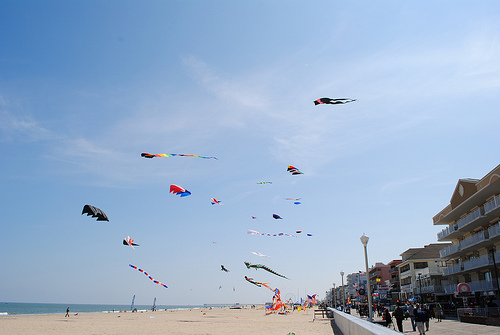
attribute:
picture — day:
[2, 0, 477, 326]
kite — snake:
[129, 264, 166, 291]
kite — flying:
[311, 95, 355, 107]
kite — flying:
[139, 145, 221, 163]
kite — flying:
[241, 258, 286, 280]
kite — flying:
[285, 157, 302, 179]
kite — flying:
[246, 228, 312, 237]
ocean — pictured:
[1, 299, 228, 316]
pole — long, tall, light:
[333, 201, 374, 333]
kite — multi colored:
[312, 95, 358, 105]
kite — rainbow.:
[298, 93, 357, 115]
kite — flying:
[232, 54, 364, 138]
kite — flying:
[99, 248, 199, 293]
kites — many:
[78, 86, 361, 303]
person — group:
[380, 306, 395, 326]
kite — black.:
[68, 194, 134, 241]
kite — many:
[290, 87, 372, 134]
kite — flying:
[308, 86, 360, 114]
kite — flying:
[126, 136, 231, 167]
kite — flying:
[79, 194, 114, 226]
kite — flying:
[118, 229, 143, 249]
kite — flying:
[115, 256, 175, 294]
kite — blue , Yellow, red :
[170, 183, 189, 197]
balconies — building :
[431, 174, 499, 315]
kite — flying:
[308, 86, 366, 110]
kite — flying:
[135, 148, 219, 165]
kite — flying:
[78, 198, 108, 226]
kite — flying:
[118, 233, 142, 251]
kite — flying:
[282, 162, 302, 182]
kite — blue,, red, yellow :
[244, 71, 385, 126]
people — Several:
[308, 277, 443, 334]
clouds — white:
[59, 64, 320, 189]